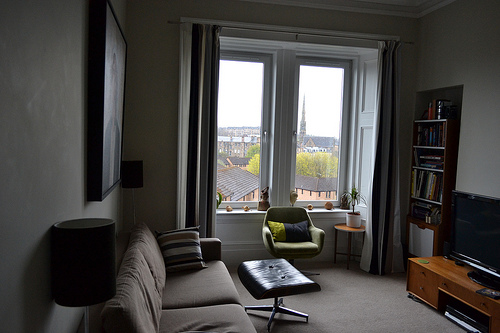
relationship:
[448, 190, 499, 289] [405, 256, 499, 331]
television on entertainment consol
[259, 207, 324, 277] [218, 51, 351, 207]
chair near window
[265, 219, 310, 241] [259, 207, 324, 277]
pillow in chair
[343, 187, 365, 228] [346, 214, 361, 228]
plant inside pot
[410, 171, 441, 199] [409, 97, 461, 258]
books inside bookcase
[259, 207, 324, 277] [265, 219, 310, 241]
chair holding pillow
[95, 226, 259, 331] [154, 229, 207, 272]
sofa has pillow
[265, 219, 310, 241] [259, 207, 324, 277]
pillow on chair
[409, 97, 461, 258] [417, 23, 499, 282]
bookcase on wall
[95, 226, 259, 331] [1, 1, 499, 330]
sofa in living room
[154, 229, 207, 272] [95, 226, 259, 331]
pillow on sofa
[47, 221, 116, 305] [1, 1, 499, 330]
lamp shade in living room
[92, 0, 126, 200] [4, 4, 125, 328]
painting on wall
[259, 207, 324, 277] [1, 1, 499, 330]
chair in living room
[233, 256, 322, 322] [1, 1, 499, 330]
seat in living room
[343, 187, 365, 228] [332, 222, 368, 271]
plant on table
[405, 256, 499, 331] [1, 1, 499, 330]
entertainment consol in living room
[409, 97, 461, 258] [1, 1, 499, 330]
bookcase in living room